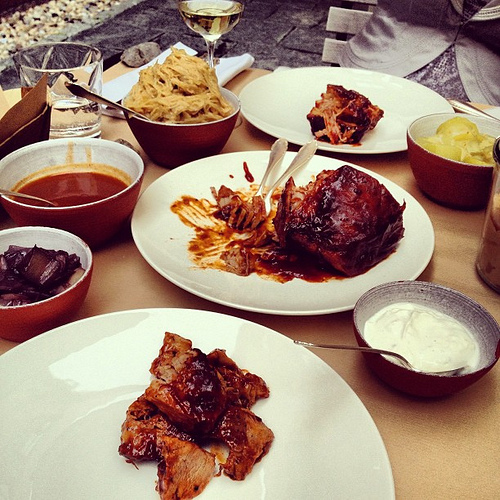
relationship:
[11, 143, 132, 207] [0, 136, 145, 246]
soup in bowl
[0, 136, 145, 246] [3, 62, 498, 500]
bowl on table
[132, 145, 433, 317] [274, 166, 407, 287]
plate has food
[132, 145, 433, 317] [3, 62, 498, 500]
plate on table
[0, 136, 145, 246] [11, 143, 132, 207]
bowl has soup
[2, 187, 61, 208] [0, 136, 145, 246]
spoon in bowl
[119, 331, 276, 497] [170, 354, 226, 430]
meat has sauce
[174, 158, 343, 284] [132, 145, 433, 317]
sauce on plate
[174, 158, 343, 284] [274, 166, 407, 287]
sauce next to meat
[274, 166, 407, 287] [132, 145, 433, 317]
meat on plate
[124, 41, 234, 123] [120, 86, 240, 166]
puree in bowl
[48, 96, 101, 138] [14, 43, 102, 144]
water in glass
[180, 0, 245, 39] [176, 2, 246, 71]
wine in stemmed glass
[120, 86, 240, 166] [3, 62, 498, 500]
bowl on table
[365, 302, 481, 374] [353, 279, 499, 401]
cream in bowl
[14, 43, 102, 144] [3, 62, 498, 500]
glass on table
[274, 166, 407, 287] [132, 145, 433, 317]
food on plate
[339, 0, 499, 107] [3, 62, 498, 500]
person next to table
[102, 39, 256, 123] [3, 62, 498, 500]
napkin on table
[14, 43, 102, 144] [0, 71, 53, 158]
glass next to napkin holder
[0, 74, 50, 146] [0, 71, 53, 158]
napkin in napkin holder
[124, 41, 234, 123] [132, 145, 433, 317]
puree behind plate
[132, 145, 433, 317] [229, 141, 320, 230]
plate has fork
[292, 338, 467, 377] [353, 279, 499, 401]
spoon in bowl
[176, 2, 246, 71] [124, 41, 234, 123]
stemmed glass behind puree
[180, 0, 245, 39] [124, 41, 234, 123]
wine behind puree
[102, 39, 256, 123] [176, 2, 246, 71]
napkin next to stemmed glass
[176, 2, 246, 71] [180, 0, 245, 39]
stemmed glass has wine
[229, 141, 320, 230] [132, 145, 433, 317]
fork on plate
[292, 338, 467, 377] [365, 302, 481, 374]
spoon in cream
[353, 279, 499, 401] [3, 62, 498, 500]
bowl on table